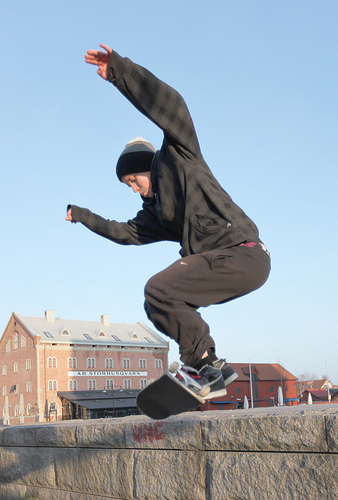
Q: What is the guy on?
A: Board.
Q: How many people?
A: 1.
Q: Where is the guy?
A: In the air.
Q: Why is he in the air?
A: He jumped.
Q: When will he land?
A: Soon.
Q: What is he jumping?
A: A wall.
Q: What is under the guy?
A: The wall.